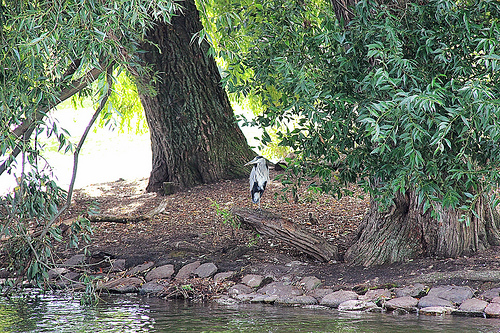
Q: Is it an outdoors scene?
A: Yes, it is outdoors.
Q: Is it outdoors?
A: Yes, it is outdoors.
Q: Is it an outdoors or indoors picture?
A: It is outdoors.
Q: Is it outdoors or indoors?
A: It is outdoors.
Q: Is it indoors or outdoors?
A: It is outdoors.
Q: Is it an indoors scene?
A: No, it is outdoors.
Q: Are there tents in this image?
A: No, there are no tents.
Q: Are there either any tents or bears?
A: No, there are no tents or bears.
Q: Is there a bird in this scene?
A: Yes, there is a bird.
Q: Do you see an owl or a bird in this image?
A: Yes, there is a bird.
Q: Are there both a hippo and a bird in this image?
A: No, there is a bird but no hippoes.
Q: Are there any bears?
A: No, there are no bears.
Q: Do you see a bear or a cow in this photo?
A: No, there are no bears or cows.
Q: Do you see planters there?
A: No, there are no planters.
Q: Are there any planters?
A: No, there are no planters.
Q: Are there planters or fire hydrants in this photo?
A: No, there are no planters or fire hydrants.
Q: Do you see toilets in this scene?
A: No, there are no toilets.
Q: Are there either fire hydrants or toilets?
A: No, there are no toilets or fire hydrants.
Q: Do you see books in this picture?
A: No, there are no books.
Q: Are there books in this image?
A: No, there are no books.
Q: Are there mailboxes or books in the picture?
A: No, there are no books or mailboxes.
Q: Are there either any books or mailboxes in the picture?
A: No, there are no books or mailboxes.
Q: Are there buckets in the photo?
A: No, there are no buckets.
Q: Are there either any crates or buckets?
A: No, there are no buckets or crates.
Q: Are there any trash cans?
A: No, there are no trash cans.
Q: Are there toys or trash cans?
A: No, there are no trash cans or toys.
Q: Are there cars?
A: No, there are no cars.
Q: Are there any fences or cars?
A: No, there are no cars or fences.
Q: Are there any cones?
A: No, there are no cones.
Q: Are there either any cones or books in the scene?
A: No, there are no cones or books.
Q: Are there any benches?
A: No, there are no benches.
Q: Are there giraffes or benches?
A: No, there are no benches or giraffes.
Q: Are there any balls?
A: No, there are no balls.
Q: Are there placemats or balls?
A: No, there are no balls or placemats.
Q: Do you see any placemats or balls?
A: No, there are no balls or placemats.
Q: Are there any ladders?
A: No, there are no ladders.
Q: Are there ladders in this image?
A: No, there are no ladders.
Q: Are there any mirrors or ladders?
A: No, there are no ladders or mirrors.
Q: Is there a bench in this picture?
A: No, there are no benches.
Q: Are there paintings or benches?
A: No, there are no benches or paintings.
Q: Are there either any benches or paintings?
A: No, there are no benches or paintings.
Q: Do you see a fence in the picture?
A: No, there are no fences.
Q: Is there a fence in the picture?
A: No, there are no fences.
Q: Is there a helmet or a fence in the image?
A: No, there are no fences or helmets.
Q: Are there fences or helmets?
A: No, there are no fences or helmets.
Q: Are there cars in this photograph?
A: No, there are no cars.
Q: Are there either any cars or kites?
A: No, there are no cars or kites.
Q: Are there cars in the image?
A: No, there are no cars.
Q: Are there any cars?
A: No, there are no cars.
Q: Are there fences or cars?
A: No, there are no cars or fences.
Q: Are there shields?
A: No, there are no shields.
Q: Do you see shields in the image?
A: No, there are no shields.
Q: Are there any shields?
A: No, there are no shields.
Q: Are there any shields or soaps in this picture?
A: No, there are no shields or soaps.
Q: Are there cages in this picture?
A: No, there are no cages.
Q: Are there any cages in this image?
A: No, there are no cages.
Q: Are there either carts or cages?
A: No, there are no cages or carts.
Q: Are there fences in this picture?
A: No, there are no fences.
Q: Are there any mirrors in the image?
A: No, there are no mirrors.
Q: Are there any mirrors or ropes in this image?
A: No, there are no mirrors or ropes.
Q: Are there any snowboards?
A: No, there are no snowboards.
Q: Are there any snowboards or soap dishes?
A: No, there are no snowboards or soap dishes.